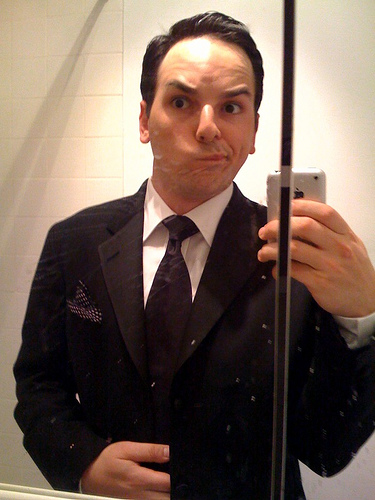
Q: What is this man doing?
A: Taking a picture.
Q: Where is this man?
A: In a bathroom.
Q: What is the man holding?
A: A phone.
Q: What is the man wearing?
A: A suit.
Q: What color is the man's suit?
A: Black.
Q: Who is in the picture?
A: A man.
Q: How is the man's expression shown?
A: Frowning.